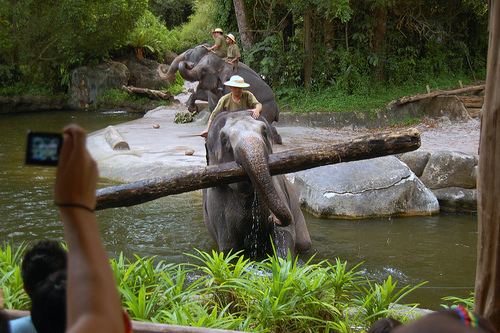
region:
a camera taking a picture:
[11, 108, 79, 175]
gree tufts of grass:
[200, 251, 379, 331]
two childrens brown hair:
[4, 233, 94, 330]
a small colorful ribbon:
[430, 291, 480, 328]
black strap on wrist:
[48, 193, 111, 232]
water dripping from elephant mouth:
[163, 178, 290, 294]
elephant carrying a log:
[82, 115, 432, 235]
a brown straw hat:
[213, 74, 258, 91]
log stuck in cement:
[104, 116, 136, 168]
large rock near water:
[327, 160, 445, 277]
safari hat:
[221, 73, 251, 88]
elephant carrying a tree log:
[94, 108, 424, 267]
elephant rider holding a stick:
[175, 71, 263, 140]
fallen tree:
[384, 81, 484, 108]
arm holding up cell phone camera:
[21, 125, 125, 332]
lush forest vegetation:
[1, 240, 431, 331]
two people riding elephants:
[156, 23, 283, 125]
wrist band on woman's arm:
[52, 118, 124, 331]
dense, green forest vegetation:
[1, 2, 488, 117]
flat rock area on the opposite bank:
[79, 100, 479, 225]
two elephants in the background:
[157, 27, 279, 122]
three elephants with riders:
[157, 41, 310, 260]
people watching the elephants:
[2, 125, 131, 330]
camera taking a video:
[28, 129, 67, 165]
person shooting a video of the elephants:
[27, 125, 131, 331]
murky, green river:
[3, 111, 493, 310]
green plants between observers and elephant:
[2, 253, 432, 331]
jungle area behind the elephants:
[6, 0, 491, 113]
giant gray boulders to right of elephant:
[281, 151, 482, 218]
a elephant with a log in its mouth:
[168, 107, 303, 246]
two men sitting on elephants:
[161, 20, 268, 89]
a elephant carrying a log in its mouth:
[108, 104, 445, 232]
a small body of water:
[60, 177, 473, 297]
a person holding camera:
[0, 100, 118, 277]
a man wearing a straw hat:
[203, 65, 266, 122]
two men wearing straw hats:
[188, 26, 257, 55]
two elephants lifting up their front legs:
[146, 12, 255, 127]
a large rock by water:
[304, 140, 468, 235]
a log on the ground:
[97, 112, 145, 160]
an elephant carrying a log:
[71, 71, 425, 261]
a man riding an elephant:
[96, 71, 422, 265]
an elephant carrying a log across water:
[94, 73, 421, 273]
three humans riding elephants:
[151, 23, 325, 264]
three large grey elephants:
[154, 41, 314, 263]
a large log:
[93, 129, 422, 214]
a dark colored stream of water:
[1, 104, 478, 316]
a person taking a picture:
[20, 125, 127, 331]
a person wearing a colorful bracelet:
[389, 307, 499, 331]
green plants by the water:
[0, 233, 475, 331]